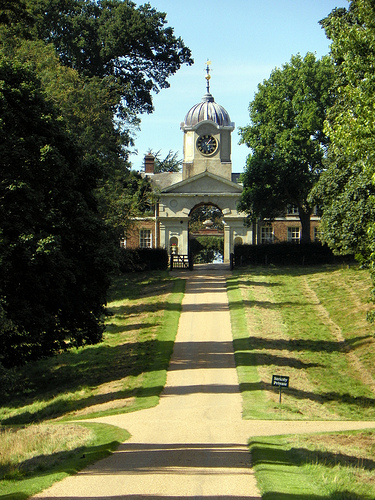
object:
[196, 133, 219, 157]
clock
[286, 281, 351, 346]
grass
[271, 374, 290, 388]
sign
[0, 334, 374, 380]
shadows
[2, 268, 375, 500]
ground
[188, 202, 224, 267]
entrance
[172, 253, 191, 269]
gate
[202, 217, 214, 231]
fountain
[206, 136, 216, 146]
clock hands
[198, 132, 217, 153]
numbers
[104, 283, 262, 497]
path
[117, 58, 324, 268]
building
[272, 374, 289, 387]
private property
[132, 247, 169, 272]
shrub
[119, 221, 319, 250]
many windows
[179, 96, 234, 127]
roof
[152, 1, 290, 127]
sky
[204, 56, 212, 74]
cross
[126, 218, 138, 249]
wall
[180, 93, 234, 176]
clock tower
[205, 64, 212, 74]
weather vane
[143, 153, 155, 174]
chimney